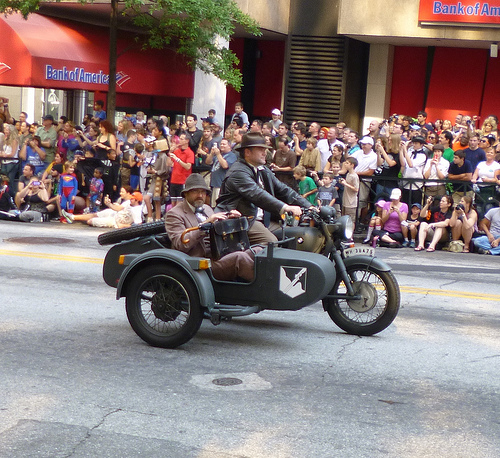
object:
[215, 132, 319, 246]
man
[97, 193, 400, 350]
motorcycle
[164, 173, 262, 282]
man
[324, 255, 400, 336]
front tire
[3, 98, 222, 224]
people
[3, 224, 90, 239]
street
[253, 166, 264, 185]
shirt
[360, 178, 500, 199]
fenc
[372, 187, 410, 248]
person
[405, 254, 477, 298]
ground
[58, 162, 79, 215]
child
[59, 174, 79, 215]
superman outfit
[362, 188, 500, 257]
people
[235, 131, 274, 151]
fedora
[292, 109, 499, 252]
people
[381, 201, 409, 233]
tshirt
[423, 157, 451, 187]
shirt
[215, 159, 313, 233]
jacket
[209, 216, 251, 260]
bag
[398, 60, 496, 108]
hat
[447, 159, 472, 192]
shirt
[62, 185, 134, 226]
man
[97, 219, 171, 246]
wheel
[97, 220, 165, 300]
back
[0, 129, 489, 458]
event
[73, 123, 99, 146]
people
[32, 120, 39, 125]
camera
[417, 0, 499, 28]
board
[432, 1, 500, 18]
name of a bank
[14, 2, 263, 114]
tree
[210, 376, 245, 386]
drain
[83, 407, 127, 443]
crack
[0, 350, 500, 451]
asphalt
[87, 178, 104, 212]
costume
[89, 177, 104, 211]
superman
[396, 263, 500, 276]
curb